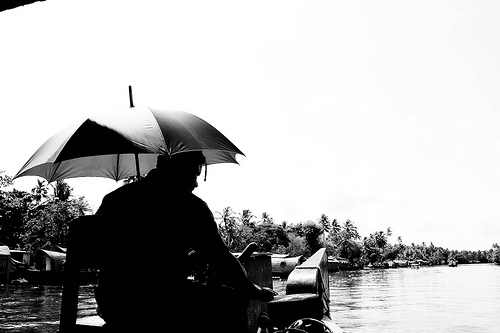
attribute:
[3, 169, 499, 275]
trees — in a row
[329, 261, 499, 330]
water — open, calm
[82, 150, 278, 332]
man — sitting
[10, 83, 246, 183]
umbrella — striped, open, giving man shade, black, white, multiple shades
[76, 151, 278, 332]
person — sitting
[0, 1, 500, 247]
sky — cloudy